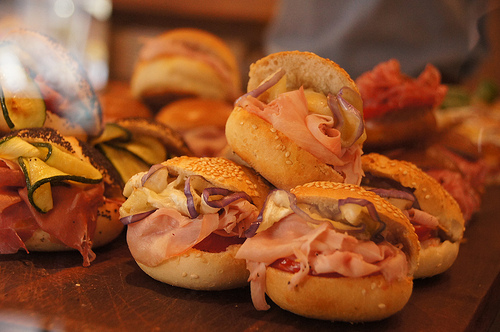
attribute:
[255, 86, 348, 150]
meat — piled, on small sandwich, on bread, on sandwich, pink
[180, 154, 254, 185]
seeds — on small sandwich, on a bun, on top of bun, black, white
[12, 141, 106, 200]
vegetable — green, on sandwich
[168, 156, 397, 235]
buns — on sandwich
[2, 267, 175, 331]
table — wooden, made of wood, on wood, wood, brown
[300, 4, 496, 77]
person — in background, blue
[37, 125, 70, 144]
seeds — black on sandwich, black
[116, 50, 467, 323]
sandwiches — on top of table, on table, on display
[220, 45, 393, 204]
sandwich — on top, on table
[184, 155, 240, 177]
sesame seeds — on bread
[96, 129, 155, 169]
zucchini — sliced, on sandwich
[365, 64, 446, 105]
tomatoes — on bread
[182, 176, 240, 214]
onions — on sandwich, purple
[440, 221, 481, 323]
table — brown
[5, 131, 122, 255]
sandwich — open, on table, small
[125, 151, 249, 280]
sandwich — ham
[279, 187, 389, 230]
onion — sliced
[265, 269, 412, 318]
bun — on bottom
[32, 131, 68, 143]
poppy seeds — `on sandwich